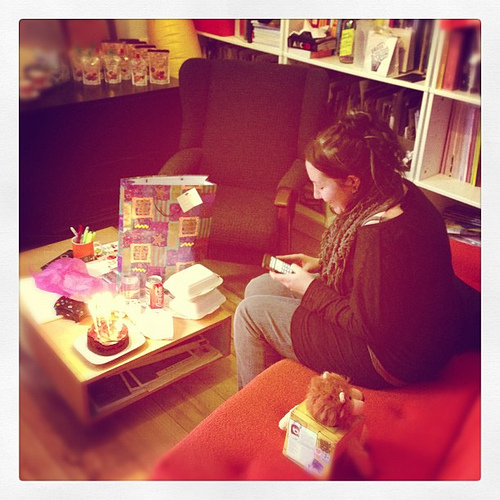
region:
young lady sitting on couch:
[227, 108, 498, 394]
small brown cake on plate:
[84, 316, 130, 359]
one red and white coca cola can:
[141, 274, 166, 315]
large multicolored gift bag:
[115, 171, 216, 306]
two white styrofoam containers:
[162, 261, 227, 321]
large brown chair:
[157, 54, 332, 275]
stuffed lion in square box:
[277, 368, 378, 479]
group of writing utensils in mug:
[64, 223, 97, 260]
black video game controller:
[51, 292, 95, 322]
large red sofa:
[134, 237, 479, 480]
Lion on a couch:
[266, 361, 415, 496]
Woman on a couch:
[271, 118, 482, 380]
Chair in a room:
[163, 61, 364, 296]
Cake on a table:
[76, 306, 133, 380]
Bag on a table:
[108, 162, 238, 286]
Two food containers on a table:
[158, 260, 245, 324]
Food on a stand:
[53, 35, 186, 95]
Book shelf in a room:
[277, 21, 498, 209]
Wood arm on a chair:
[261, 179, 308, 260]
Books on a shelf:
[333, 74, 445, 174]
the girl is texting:
[252, 230, 327, 337]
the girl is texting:
[263, 247, 355, 364]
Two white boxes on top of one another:
[168, 269, 223, 316]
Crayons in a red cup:
[66, 223, 102, 249]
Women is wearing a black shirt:
[338, 215, 448, 348]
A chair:
[188, 68, 294, 180]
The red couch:
[200, 406, 280, 471]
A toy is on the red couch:
[275, 374, 378, 470]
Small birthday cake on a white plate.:
[81, 301, 132, 353]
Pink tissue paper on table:
[34, 263, 103, 294]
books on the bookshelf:
[447, 108, 480, 185]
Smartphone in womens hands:
[259, 252, 296, 282]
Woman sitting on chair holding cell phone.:
[226, 108, 470, 398]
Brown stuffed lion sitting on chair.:
[303, 363, 385, 479]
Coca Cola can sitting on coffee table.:
[142, 271, 167, 316]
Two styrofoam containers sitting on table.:
[159, 262, 234, 332]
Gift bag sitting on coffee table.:
[115, 171, 226, 291]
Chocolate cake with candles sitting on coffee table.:
[66, 291, 151, 370]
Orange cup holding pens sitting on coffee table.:
[66, 221, 103, 263]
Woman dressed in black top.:
[298, 168, 470, 379]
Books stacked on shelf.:
[431, 93, 485, 200]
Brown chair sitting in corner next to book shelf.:
[160, 52, 332, 270]